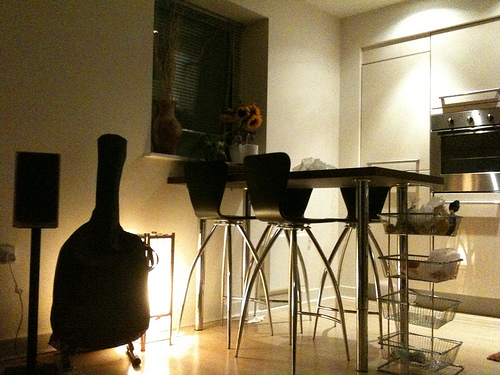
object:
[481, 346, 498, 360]
rug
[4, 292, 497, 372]
floor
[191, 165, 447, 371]
table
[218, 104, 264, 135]
flower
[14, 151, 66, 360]
speaker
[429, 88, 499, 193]
oven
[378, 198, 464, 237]
baskets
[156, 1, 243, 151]
window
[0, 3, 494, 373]
home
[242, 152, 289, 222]
back seat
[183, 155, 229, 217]
back seat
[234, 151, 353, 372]
bar stool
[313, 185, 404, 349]
bar stool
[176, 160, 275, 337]
bar stool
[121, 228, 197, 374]
glow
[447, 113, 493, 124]
knobs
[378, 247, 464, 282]
basket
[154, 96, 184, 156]
vase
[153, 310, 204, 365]
reflection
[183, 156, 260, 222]
seat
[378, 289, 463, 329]
basket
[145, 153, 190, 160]
sill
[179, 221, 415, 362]
legs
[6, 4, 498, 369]
kitchen